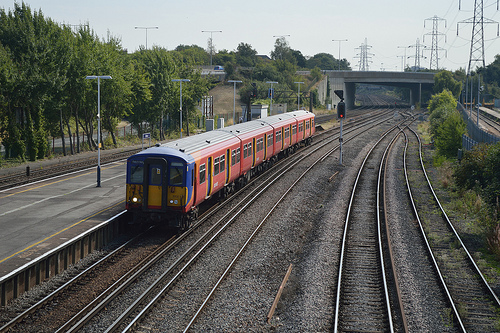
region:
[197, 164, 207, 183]
glass window on train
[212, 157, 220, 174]
glass window on train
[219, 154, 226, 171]
glass window on train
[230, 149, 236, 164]
glass window on train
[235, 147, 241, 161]
glass window on train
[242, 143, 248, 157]
glass window on train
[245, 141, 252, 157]
glass window on train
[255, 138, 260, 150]
glass window on train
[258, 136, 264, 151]
glass window on train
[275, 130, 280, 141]
glass window on train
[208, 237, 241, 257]
this is the railway track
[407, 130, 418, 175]
this is the railway track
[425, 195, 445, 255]
this is the railway track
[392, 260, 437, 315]
this is the railway track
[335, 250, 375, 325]
this is the railway track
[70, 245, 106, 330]
this is the railway track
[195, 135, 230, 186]
the train is red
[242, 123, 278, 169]
the train is red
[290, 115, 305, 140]
the train is red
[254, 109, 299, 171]
the train is red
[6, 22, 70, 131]
green leaves on the trees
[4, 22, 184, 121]
several trees beside the road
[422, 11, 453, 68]
electrical wire towers in background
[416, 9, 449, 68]
electrical wire towers are metal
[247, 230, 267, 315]
gray gravel between railroads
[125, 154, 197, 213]
front of railcar is blue and yellow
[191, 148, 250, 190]
side of railcar is red in color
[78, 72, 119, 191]
light pole on railway decking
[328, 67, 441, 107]
bridge over railroad in background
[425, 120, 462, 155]
green bushes beside railroad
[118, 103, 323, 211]
red train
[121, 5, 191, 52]
white clouds in blue sky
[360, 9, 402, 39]
white clouds in blue sky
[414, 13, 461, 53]
white clouds in blue sky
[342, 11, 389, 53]
white clouds in blue sky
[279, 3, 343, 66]
white clouds in blue sky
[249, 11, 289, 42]
white clouds in blue sky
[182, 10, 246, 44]
white clouds in blue sky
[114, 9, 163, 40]
white clouds in blue sky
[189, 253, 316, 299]
tacks